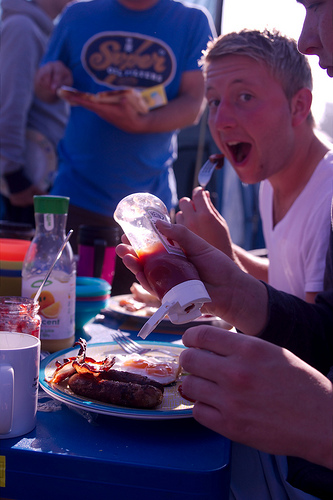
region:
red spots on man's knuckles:
[227, 366, 253, 406]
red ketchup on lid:
[177, 302, 197, 314]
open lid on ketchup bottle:
[130, 295, 206, 332]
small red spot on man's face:
[252, 161, 272, 177]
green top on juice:
[25, 187, 78, 215]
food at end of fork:
[201, 141, 237, 170]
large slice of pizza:
[46, 74, 158, 119]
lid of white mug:
[13, 334, 45, 351]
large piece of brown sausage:
[63, 364, 164, 403]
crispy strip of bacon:
[58, 343, 112, 370]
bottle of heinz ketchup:
[111, 189, 214, 340]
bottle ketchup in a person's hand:
[111, 191, 215, 341]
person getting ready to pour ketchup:
[111, 191, 212, 338]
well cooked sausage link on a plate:
[92, 379, 161, 409]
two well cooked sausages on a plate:
[66, 367, 165, 407]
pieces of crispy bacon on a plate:
[51, 336, 116, 383]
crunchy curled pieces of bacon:
[42, 335, 117, 387]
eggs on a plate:
[103, 350, 181, 385]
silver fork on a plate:
[108, 329, 183, 362]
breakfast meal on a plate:
[36, 337, 203, 418]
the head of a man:
[187, 20, 310, 180]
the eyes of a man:
[194, 80, 280, 122]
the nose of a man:
[199, 104, 249, 149]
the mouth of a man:
[218, 116, 272, 187]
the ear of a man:
[274, 68, 329, 124]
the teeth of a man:
[212, 131, 272, 162]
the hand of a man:
[180, 294, 319, 478]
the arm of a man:
[75, 27, 224, 140]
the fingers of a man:
[165, 289, 267, 422]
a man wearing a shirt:
[238, 110, 329, 294]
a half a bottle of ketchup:
[111, 192, 211, 338]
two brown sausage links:
[67, 372, 163, 408]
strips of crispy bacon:
[48, 338, 115, 385]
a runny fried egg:
[110, 349, 180, 386]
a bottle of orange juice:
[24, 192, 75, 350]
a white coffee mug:
[0, 330, 40, 438]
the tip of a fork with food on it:
[196, 153, 219, 188]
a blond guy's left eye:
[239, 89, 256, 105]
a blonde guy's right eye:
[205, 96, 221, 109]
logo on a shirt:
[80, 27, 176, 92]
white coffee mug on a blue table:
[0, 331, 39, 444]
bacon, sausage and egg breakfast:
[36, 332, 216, 421]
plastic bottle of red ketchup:
[112, 193, 211, 344]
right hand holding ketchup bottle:
[111, 215, 270, 338]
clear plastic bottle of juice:
[21, 196, 75, 352]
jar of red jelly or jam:
[0, 298, 39, 339]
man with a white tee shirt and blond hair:
[150, 25, 328, 308]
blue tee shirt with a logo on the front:
[30, 1, 210, 228]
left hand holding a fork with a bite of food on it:
[170, 150, 232, 250]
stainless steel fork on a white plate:
[112, 329, 175, 364]